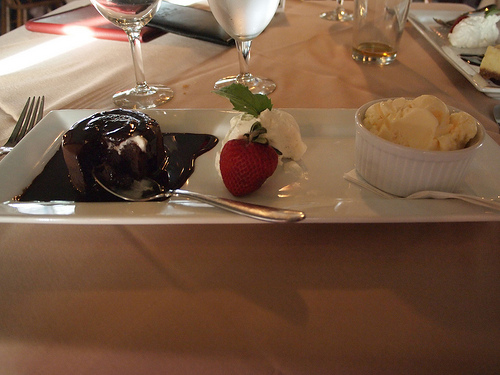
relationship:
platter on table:
[0, 109, 500, 225] [0, 1, 499, 374]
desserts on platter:
[11, 83, 486, 204] [0, 109, 500, 225]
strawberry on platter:
[219, 121, 282, 197] [0, 109, 500, 225]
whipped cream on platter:
[215, 108, 307, 188] [0, 109, 500, 225]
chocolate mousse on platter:
[11, 108, 219, 202] [0, 109, 500, 225]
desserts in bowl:
[361, 94, 479, 151] [355, 98, 486, 198]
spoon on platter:
[91, 167, 306, 222] [0, 109, 500, 225]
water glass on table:
[207, 1, 281, 96] [0, 1, 499, 374]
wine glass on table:
[90, 1, 175, 108] [0, 1, 499, 374]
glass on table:
[351, 0, 412, 66] [0, 1, 499, 374]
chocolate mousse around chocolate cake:
[11, 108, 219, 202] [62, 108, 166, 194]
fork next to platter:
[0, 95, 45, 155] [0, 109, 500, 225]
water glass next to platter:
[207, 1, 281, 96] [0, 109, 500, 225]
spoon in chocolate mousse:
[91, 167, 306, 222] [11, 108, 219, 202]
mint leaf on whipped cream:
[211, 83, 273, 119] [215, 108, 307, 188]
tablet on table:
[25, 3, 168, 43] [0, 1, 499, 374]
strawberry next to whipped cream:
[219, 121, 282, 197] [215, 108, 307, 188]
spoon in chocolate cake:
[91, 167, 306, 222] [62, 108, 166, 194]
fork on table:
[0, 95, 45, 155] [0, 1, 499, 374]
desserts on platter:
[448, 6, 499, 82] [399, 4, 499, 97]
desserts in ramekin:
[361, 94, 479, 151] [354, 96, 486, 197]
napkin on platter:
[344, 166, 500, 209] [0, 109, 500, 225]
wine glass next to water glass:
[90, 1, 175, 108] [207, 1, 281, 96]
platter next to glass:
[399, 4, 499, 97] [351, 0, 412, 66]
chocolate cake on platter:
[62, 108, 166, 194] [0, 109, 500, 225]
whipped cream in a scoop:
[215, 108, 307, 188] [216, 109, 306, 181]